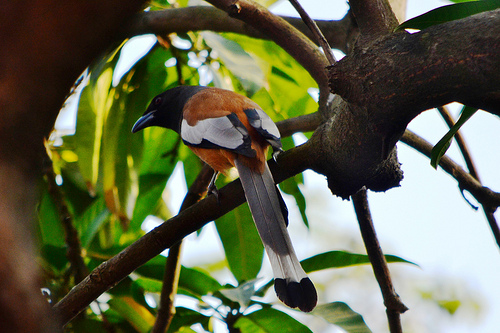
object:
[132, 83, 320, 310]
bird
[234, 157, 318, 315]
tail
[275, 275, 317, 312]
edge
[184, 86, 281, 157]
back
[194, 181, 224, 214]
foot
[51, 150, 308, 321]
branch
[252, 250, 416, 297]
leaves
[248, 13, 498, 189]
branch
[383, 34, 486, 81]
bark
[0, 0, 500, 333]
tree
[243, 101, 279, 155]
wing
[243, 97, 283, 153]
wing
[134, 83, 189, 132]
head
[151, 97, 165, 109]
eye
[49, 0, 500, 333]
sky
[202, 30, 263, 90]
leaves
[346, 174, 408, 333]
branch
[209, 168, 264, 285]
leaf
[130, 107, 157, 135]
beak